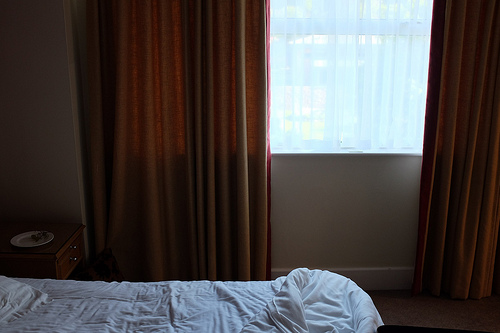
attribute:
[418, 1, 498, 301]
curtain panel — orange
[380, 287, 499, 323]
carpet — brown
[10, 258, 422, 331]
blanket — wrinkled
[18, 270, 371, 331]
sheets — white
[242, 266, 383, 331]
sheet — white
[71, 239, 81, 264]
knobs — silver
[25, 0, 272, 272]
curtain — orange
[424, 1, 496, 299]
curtain — sheer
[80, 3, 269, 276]
curtain — sheer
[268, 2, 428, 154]
curtain — sheer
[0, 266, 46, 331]
pillow — white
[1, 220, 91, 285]
end stand — wooden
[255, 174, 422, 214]
wall — white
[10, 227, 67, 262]
plate — white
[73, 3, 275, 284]
drapes — sheer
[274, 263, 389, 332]
pillow — white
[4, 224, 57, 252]
plate — white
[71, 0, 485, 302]
curtains — light white, heavy brown